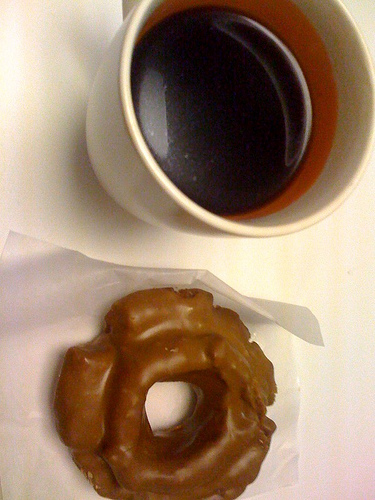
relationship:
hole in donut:
[143, 377, 211, 443] [52, 286, 277, 498]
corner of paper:
[241, 282, 335, 387] [1, 228, 324, 498]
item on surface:
[39, 261, 284, 484] [10, 201, 362, 494]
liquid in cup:
[138, 10, 315, 206] [61, 11, 373, 258]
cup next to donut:
[61, 11, 373, 258] [51, 267, 285, 494]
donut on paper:
[52, 286, 277, 498] [1, 228, 324, 498]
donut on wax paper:
[52, 286, 277, 498] [2, 226, 77, 354]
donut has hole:
[52, 286, 277, 498] [144, 377, 199, 437]